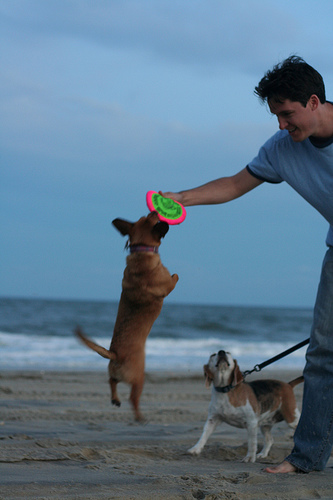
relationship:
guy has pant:
[194, 48, 332, 273] [282, 309, 327, 414]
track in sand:
[71, 397, 188, 466] [30, 406, 109, 445]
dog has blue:
[93, 189, 200, 353] [110, 234, 179, 260]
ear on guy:
[308, 79, 331, 111] [157, 55, 332, 480]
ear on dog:
[93, 198, 138, 252] [93, 189, 200, 353]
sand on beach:
[30, 406, 109, 445] [3, 364, 87, 481]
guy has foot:
[157, 55, 332, 480] [262, 420, 331, 479]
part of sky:
[138, 48, 163, 74] [67, 32, 198, 149]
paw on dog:
[171, 260, 189, 294] [93, 189, 200, 353]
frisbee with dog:
[152, 178, 197, 233] [93, 189, 200, 353]